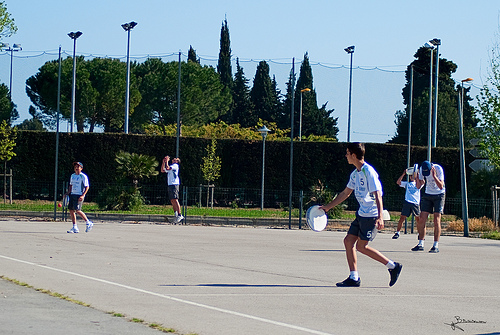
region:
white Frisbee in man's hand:
[299, 202, 340, 234]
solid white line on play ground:
[153, 284, 228, 313]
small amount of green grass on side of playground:
[35, 272, 85, 317]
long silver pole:
[245, 119, 273, 206]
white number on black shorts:
[354, 220, 413, 263]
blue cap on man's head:
[418, 154, 435, 183]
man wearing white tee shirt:
[66, 171, 101, 213]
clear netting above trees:
[217, 33, 480, 110]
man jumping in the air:
[137, 139, 198, 236]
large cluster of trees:
[48, 25, 392, 158]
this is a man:
[300, 142, 370, 284]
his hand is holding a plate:
[298, 182, 351, 232]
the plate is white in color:
[293, 204, 328, 240]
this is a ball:
[53, 202, 60, 207]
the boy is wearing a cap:
[71, 163, 80, 166]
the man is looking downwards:
[414, 163, 444, 228]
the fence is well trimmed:
[230, 136, 290, 186]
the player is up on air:
[156, 153, 181, 226]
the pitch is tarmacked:
[50, 230, 292, 286]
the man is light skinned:
[360, 243, 366, 249]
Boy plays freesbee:
[297, 126, 403, 296]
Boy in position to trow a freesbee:
[300, 125, 405, 296]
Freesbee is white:
[295, 195, 330, 232]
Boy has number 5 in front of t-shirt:
[315, 130, 415, 302]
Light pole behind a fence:
[114, 10, 145, 132]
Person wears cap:
[48, 156, 105, 238]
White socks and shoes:
[63, 220, 98, 239]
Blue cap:
[414, 157, 434, 178]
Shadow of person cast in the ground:
[159, 265, 334, 299]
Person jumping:
[157, 146, 190, 230]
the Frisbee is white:
[292, 201, 340, 241]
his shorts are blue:
[354, 215, 393, 238]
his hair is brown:
[338, 134, 376, 162]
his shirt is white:
[337, 171, 400, 223]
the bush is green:
[205, 135, 307, 175]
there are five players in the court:
[59, 134, 456, 259]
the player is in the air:
[151, 152, 208, 235]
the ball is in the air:
[43, 201, 72, 211]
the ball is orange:
[51, 201, 76, 225]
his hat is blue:
[406, 153, 454, 197]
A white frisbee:
[298, 197, 339, 240]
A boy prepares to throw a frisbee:
[298, 136, 404, 298]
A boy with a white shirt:
[52, 157, 105, 234]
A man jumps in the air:
[155, 146, 197, 231]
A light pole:
[340, 43, 362, 142]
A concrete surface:
[1, 238, 331, 334]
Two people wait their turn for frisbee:
[393, 160, 458, 250]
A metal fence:
[181, 184, 304, 229]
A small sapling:
[194, 137, 226, 211]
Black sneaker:
[331, 274, 365, 291]